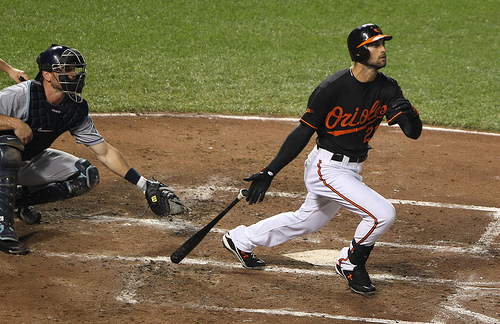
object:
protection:
[345, 239, 379, 264]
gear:
[0, 42, 104, 251]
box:
[171, 25, 422, 293]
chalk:
[444, 241, 484, 257]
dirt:
[288, 235, 336, 249]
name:
[323, 96, 393, 142]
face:
[42, 65, 90, 102]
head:
[343, 18, 391, 73]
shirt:
[298, 66, 406, 164]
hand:
[0, 58, 31, 87]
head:
[33, 42, 92, 103]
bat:
[166, 188, 253, 264]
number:
[363, 125, 379, 143]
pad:
[343, 239, 378, 269]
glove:
[141, 179, 189, 218]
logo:
[37, 127, 54, 136]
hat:
[347, 22, 391, 62]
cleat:
[219, 234, 267, 271]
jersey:
[290, 64, 424, 162]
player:
[221, 21, 423, 294]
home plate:
[282, 244, 344, 269]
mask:
[55, 45, 87, 103]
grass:
[0, 6, 500, 134]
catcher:
[4, 40, 188, 260]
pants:
[219, 142, 399, 275]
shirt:
[1, 77, 108, 159]